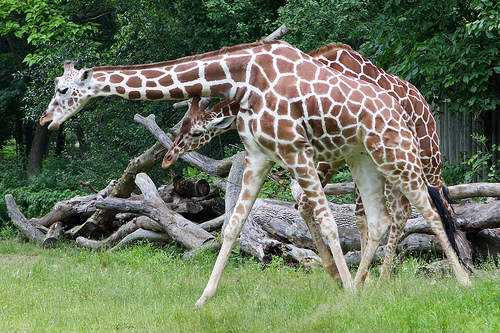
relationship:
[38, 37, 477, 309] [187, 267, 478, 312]
giraffe has feet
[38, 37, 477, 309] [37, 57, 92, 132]
giraffe has a head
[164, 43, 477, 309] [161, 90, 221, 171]
giraffe has a head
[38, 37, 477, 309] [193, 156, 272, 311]
giraffe has a leg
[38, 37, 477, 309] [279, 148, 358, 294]
giraffe has a leg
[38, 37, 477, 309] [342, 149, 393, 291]
giraffe has a leg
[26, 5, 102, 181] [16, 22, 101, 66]
tree has branches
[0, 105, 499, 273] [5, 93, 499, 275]
logs are lying in a pile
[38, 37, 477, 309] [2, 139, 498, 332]
giraffe standing in a field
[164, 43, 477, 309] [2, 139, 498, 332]
giraffe standing in a field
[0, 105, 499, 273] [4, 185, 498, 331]
logs are lying on ground